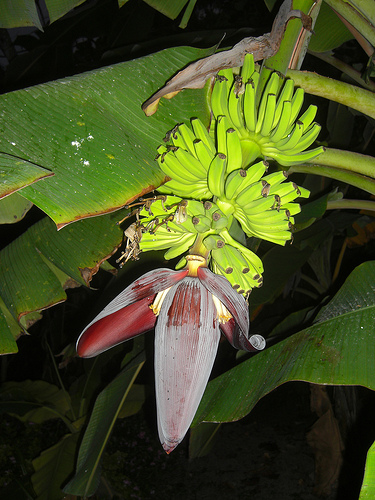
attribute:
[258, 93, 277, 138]
banana — green, yellow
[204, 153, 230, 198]
banana — green, yellow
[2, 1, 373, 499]
tree — grown, forest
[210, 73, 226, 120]
banana — yellow, green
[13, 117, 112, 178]
spots — white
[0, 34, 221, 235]
leaf — green, large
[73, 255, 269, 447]
flower — red, white, purple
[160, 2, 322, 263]
stem — green, stems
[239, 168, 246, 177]
end — brown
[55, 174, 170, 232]
edge — brown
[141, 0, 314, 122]
leaf — brown, curled up, shriveled, grey, bird